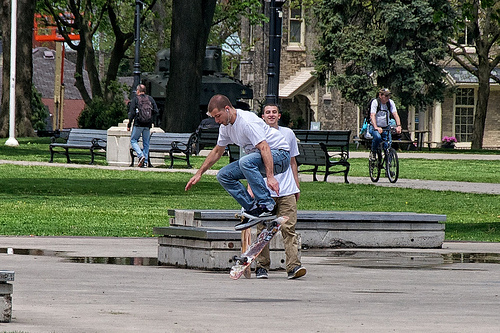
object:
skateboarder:
[183, 93, 291, 230]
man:
[361, 81, 405, 160]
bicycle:
[365, 122, 405, 183]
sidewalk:
[78, 165, 500, 198]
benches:
[166, 209, 449, 254]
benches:
[154, 223, 311, 273]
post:
[3, 1, 24, 147]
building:
[24, 44, 113, 136]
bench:
[43, 127, 103, 165]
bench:
[127, 130, 197, 168]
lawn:
[0, 157, 123, 226]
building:
[242, 0, 499, 157]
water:
[85, 257, 153, 266]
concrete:
[24, 279, 498, 331]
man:
[123, 81, 153, 173]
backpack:
[135, 92, 155, 127]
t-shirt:
[216, 108, 291, 153]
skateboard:
[223, 215, 287, 281]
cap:
[379, 88, 392, 95]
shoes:
[243, 204, 277, 220]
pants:
[239, 185, 305, 275]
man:
[245, 98, 314, 282]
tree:
[1, 0, 37, 137]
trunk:
[168, 2, 209, 59]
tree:
[162, 1, 216, 128]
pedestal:
[105, 119, 133, 168]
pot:
[442, 142, 454, 148]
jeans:
[213, 147, 291, 210]